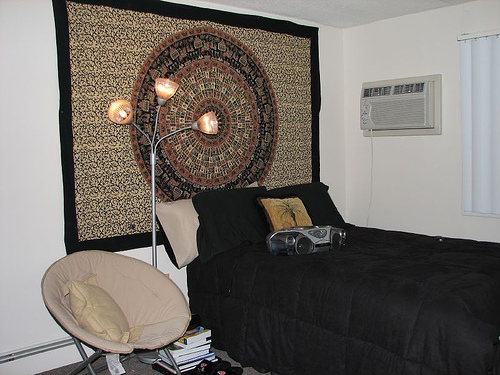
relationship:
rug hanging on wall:
[50, 0, 321, 255] [1, 2, 342, 363]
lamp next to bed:
[104, 73, 219, 361] [154, 177, 499, 374]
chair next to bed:
[42, 246, 194, 374] [154, 177, 499, 374]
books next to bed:
[150, 323, 222, 374] [154, 177, 499, 374]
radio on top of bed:
[262, 220, 346, 257] [154, 177, 499, 374]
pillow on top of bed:
[256, 194, 314, 232] [154, 177, 499, 374]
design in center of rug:
[125, 24, 280, 203] [50, 0, 321, 255]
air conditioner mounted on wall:
[357, 72, 442, 140] [341, 1, 499, 246]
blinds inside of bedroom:
[455, 28, 497, 215] [1, 1, 499, 374]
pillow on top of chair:
[62, 274, 134, 344] [42, 246, 194, 374]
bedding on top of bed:
[188, 178, 499, 373] [154, 177, 499, 374]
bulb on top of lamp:
[118, 107, 130, 119] [104, 73, 219, 361]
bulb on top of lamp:
[208, 118, 216, 131] [104, 73, 219, 361]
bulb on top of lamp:
[159, 80, 171, 97] [104, 73, 219, 361]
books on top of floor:
[150, 323, 222, 374] [32, 338, 268, 374]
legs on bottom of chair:
[65, 330, 181, 374] [42, 246, 194, 374]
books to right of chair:
[150, 323, 222, 374] [42, 246, 194, 374]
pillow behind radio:
[256, 194, 314, 232] [262, 220, 346, 257]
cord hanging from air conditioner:
[360, 127, 376, 228] [357, 72, 442, 140]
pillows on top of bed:
[151, 177, 354, 269] [154, 177, 499, 374]